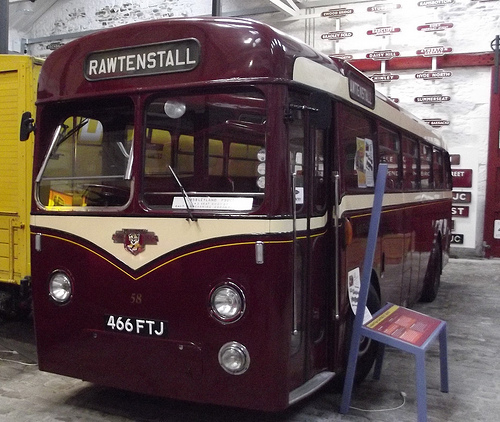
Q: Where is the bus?
A: In a shop.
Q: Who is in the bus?
A: No people.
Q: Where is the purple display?
A: Next to the bus.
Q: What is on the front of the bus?
A: A window.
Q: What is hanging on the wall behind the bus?
A: A sign.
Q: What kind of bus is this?
A: A maroon city bus.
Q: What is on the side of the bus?
A: A door.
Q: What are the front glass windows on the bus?
A: Windshields.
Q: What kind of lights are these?
A: Front headlights.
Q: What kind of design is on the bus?
A: A white stripe.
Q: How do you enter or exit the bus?
A: Through the door.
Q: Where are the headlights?
A: On the front of the bus.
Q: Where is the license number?
A: On bottom front.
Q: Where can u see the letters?
A: On top of front windows.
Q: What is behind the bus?
A: Several signs.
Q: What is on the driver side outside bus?
A: Blue desk.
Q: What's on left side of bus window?
A: Mirror.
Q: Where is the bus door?
A: Next to the desk.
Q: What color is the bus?
A: Maroon.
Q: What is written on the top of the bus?
A: Rawtenstall.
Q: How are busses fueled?
A: Gas.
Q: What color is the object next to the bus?
A: Yellow.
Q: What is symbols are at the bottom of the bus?
A: 466FTJ.